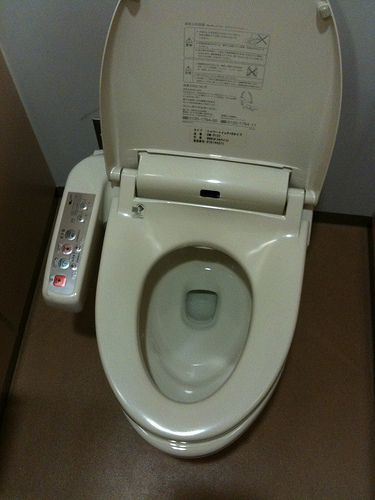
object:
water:
[135, 240, 255, 405]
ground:
[50, 433, 120, 497]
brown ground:
[277, 406, 320, 488]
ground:
[331, 88, 348, 112]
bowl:
[136, 241, 252, 406]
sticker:
[131, 203, 145, 220]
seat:
[95, 166, 309, 442]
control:
[47, 192, 96, 295]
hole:
[199, 189, 219, 200]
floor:
[304, 340, 367, 475]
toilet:
[43, 0, 345, 461]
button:
[53, 202, 87, 286]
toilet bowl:
[105, 215, 305, 440]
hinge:
[110, 147, 318, 216]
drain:
[185, 289, 219, 326]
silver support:
[43, 189, 100, 308]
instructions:
[182, 19, 271, 146]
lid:
[99, 3, 343, 211]